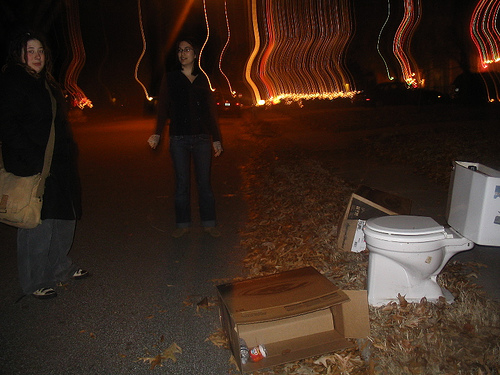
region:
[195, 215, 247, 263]
left shoe of woman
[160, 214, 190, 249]
right shoe of woman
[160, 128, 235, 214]
pants on the woman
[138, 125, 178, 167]
right hand of woman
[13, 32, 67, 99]
head of the woman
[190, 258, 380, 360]
broken box by toilet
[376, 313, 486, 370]
leaves by the toilet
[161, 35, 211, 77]
head of woman with glasses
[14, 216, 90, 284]
gray pants on woman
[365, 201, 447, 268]
top of white toilet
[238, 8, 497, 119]
waves of light in the night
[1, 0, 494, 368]
it is night time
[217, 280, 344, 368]
a cardboard box with plastic bottles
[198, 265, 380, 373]
a cardboard box with trash inside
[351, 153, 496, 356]
a broken toilet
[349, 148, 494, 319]
a toilet with no tank lid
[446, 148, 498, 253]
the tank lid is missing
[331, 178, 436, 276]
a cardboard box behind the toilet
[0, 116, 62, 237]
a tan colored messenger bag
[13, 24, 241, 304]
two women walking on the street at night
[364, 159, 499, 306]
white toilet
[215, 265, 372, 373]
brown cardboard box in front of toilet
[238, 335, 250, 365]
plastic water bottle inside box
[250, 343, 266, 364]
red container inside box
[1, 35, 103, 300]
person standing near toilet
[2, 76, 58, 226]
large canvas cross-body bag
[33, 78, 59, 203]
long strap on bag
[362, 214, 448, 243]
toilet seat lid is closed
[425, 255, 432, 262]
tan spot on toilet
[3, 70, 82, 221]
person wearing a black coat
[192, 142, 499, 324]
toilet outside on roadside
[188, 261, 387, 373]
cardboard box with trash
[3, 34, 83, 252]
woman with messenger bag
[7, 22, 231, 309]
women standing on road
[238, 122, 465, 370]
roadside strewn with fallen leaves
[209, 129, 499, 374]
trash on side of road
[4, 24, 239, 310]
women on dark road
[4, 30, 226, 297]
women wearing blue jeans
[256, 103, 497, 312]
sidewalks next to roadside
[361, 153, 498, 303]
toilet without tank lid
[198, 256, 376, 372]
A brown box on the ground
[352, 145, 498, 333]
A white toilet on the ground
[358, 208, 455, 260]
A white toilet seat cover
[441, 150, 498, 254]
A toilet tank with no top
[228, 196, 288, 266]
Brown leaves on the side of the road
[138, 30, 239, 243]
A woman standing in the road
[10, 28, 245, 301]
Two women standing in the road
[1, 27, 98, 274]
A women carrying a brown purse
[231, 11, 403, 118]
Red and orange lights in the background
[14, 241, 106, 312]
A woman's white sandals